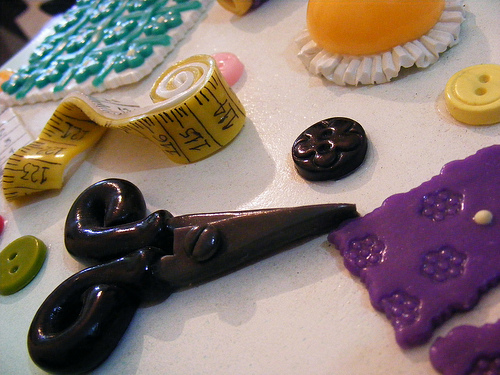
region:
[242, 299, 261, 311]
the view of a white wall and chairs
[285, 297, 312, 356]
the view of a white wall and chairs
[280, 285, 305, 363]
the view of a white wall and chairs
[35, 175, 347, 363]
this is a pair of scissors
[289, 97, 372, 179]
this is a button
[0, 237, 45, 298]
this is a button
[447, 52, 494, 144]
this is a button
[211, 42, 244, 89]
this is a button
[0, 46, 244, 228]
this is a tape measure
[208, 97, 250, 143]
a number ark on the tape measure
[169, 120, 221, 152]
a number ark on the tape measure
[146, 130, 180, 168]
a number ark on the tape measure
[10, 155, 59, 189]
a number ark on the tape measure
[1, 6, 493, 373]
the top of a cake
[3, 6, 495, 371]
designs on top a cake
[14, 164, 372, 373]
a black scissor on cake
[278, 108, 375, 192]
a black button on cake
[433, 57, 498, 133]
a yellow button on cake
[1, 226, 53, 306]
a green button on cake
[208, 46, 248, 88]
a pink button on cake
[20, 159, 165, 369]
the handles of scissors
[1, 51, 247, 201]
a measuring tape on a cake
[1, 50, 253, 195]
measuring tape has black letters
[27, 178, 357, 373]
Black pair of scissors.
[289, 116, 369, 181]
Black circle with flower on it.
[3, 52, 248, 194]
Yellow and white measuring tape with black numbers.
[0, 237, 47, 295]
A round green button.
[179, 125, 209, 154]
Black number 115.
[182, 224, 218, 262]
Black bolt on the scissors.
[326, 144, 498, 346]
Long purple piece of icing with flowers on it.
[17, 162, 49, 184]
Number 123 on a measuring tape.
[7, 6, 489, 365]
decorations formed from glossy clay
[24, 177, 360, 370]
dark handle and blades on scissors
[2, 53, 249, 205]
curled and twisted yellow measuring tape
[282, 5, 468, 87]
orange pin cushion with white ruffles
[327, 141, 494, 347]
flower design stamped onto purple surface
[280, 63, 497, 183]
round yellow and black buttons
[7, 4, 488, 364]
white surface displaying craft items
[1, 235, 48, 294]
round olive-green button with two holes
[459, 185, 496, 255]
white dot on purple surface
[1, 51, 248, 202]
Measuring tape cake decoration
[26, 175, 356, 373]
Black handle scissors made of marzipan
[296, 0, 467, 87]
Yellow and white cake decoration that looks like pin cushion